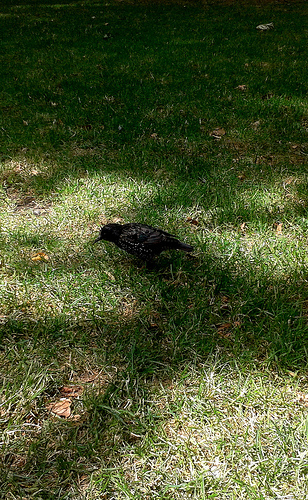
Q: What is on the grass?
A: Ray of sunlight.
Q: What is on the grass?
A: Fallen leaves.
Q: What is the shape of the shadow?
A: V shape.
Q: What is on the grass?
A: A bird.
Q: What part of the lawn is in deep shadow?
A: The back part.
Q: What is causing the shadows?
A: The sunlight through the trees.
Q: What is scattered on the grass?
A: Leaves.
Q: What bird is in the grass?
A: A crow.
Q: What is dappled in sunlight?
A: The grass.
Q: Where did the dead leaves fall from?
A: The tree above.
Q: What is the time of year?
A: Summertime.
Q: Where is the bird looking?
A: At the ground.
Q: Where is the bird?
A: On the ground.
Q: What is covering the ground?
A: Grass.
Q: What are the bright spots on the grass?
A: Sunshine.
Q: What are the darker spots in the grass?
A: Shadows.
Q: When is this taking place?
A: Daytime.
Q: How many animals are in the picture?
A: One.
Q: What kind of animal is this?
A: Bird.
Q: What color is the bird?
A: Black.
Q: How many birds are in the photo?
A: One.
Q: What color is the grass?
A: Green.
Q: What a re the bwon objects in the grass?
A: Leaves.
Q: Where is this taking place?
A: In a grass field.